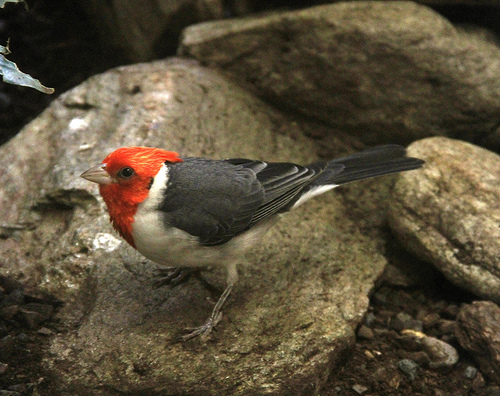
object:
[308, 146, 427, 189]
tail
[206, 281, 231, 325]
leg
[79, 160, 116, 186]
beak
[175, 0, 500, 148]
rock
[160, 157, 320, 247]
wing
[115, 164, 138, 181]
eye